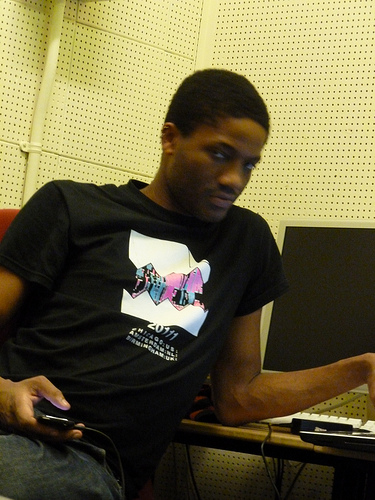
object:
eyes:
[243, 158, 256, 172]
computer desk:
[171, 418, 374, 496]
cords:
[185, 439, 203, 498]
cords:
[260, 422, 281, 499]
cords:
[279, 458, 285, 494]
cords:
[283, 461, 307, 499]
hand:
[9, 374, 85, 439]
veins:
[229, 387, 243, 409]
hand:
[364, 351, 374, 407]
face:
[164, 120, 266, 223]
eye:
[200, 145, 229, 160]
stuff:
[299, 428, 374, 451]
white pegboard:
[1, 0, 375, 238]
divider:
[0, 0, 374, 218]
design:
[119, 227, 212, 337]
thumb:
[26, 374, 71, 411]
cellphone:
[33, 398, 76, 428]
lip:
[208, 198, 233, 210]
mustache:
[203, 185, 236, 197]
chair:
[0, 208, 23, 240]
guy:
[0, 68, 374, 499]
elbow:
[209, 355, 274, 427]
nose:
[217, 162, 245, 195]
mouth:
[207, 188, 233, 209]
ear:
[159, 122, 177, 155]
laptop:
[260, 215, 374, 451]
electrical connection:
[289, 417, 354, 436]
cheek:
[165, 147, 215, 209]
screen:
[262, 225, 375, 370]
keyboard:
[290, 410, 375, 432]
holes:
[288, 28, 292, 32]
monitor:
[259, 218, 374, 395]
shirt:
[0, 178, 290, 499]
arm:
[211, 212, 372, 427]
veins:
[251, 392, 270, 409]